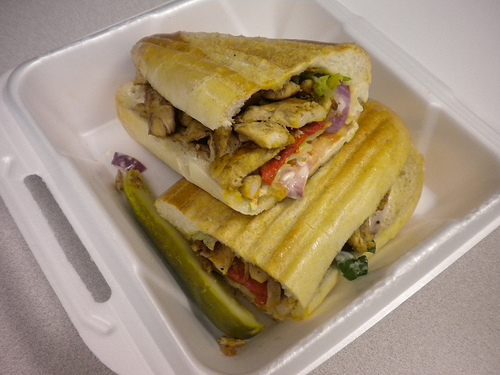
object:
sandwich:
[114, 31, 371, 214]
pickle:
[117, 167, 264, 350]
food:
[259, 122, 324, 184]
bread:
[129, 32, 370, 131]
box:
[0, 0, 500, 375]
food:
[324, 84, 350, 133]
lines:
[133, 40, 258, 86]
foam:
[1, 66, 197, 375]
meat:
[232, 122, 290, 148]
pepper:
[234, 143, 236, 146]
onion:
[279, 165, 309, 198]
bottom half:
[154, 99, 425, 323]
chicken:
[235, 96, 324, 128]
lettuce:
[338, 255, 368, 282]